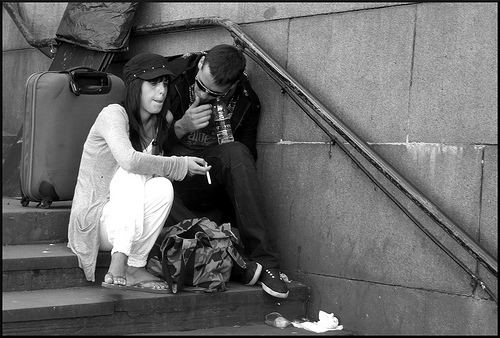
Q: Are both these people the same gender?
A: No, they are both male and female.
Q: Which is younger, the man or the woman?
A: The man is younger than the woman.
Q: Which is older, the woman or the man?
A: The woman is older than the man.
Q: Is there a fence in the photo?
A: No, there are no fences.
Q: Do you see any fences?
A: No, there are no fences.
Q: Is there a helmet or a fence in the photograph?
A: No, there are no fences or helmets.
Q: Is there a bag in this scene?
A: Yes, there is a bag.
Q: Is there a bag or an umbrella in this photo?
A: Yes, there is a bag.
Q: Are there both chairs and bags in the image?
A: No, there is a bag but no chairs.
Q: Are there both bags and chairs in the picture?
A: No, there is a bag but no chairs.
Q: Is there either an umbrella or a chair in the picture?
A: No, there are no chairs or umbrellas.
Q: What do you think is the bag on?
A: The bag is on the steps.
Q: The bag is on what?
A: The bag is on the steps.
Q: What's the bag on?
A: The bag is on the steps.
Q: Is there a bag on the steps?
A: Yes, there is a bag on the steps.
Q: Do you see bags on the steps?
A: Yes, there is a bag on the steps.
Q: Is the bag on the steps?
A: Yes, the bag is on the steps.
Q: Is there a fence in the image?
A: No, there are no fences.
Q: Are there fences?
A: No, there are no fences.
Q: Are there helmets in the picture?
A: No, there are no helmets.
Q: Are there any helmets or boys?
A: No, there are no helmets or boys.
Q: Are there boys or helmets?
A: No, there are no helmets or boys.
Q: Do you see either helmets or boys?
A: No, there are no helmets or boys.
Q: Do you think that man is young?
A: Yes, the man is young.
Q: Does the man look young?
A: Yes, the man is young.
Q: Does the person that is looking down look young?
A: Yes, the man is young.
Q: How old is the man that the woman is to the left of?
A: The man is young.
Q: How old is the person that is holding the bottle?
A: The man is young.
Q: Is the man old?
A: No, the man is young.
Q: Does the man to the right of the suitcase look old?
A: No, the man is young.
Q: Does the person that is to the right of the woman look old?
A: No, the man is young.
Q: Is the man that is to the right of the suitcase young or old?
A: The man is young.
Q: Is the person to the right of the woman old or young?
A: The man is young.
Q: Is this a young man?
A: Yes, this is a young man.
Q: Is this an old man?
A: No, this is a young man.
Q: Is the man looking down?
A: Yes, the man is looking down.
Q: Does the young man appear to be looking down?
A: Yes, the man is looking down.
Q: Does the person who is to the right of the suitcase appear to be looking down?
A: Yes, the man is looking down.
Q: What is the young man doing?
A: The man is looking down.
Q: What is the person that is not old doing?
A: The man is looking down.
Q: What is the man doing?
A: The man is looking down.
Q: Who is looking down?
A: The man is looking down.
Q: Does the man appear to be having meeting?
A: No, the man is looking down.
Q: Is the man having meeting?
A: No, the man is looking down.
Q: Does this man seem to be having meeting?
A: No, the man is looking down.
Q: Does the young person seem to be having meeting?
A: No, the man is looking down.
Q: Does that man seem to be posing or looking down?
A: The man is looking down.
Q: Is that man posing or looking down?
A: The man is looking down.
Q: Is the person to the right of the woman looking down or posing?
A: The man is looking down.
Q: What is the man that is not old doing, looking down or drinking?
A: The man is looking down.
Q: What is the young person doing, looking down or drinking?
A: The man is looking down.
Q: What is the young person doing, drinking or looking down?
A: The man is looking down.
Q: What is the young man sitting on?
A: The man is sitting on the steps.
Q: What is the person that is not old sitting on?
A: The man is sitting on the steps.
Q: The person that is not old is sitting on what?
A: The man is sitting on the steps.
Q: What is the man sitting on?
A: The man is sitting on the steps.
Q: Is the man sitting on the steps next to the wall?
A: Yes, the man is sitting on the steps.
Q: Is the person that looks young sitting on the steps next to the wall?
A: Yes, the man is sitting on the steps.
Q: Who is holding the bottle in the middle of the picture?
A: The man is holding the bottle.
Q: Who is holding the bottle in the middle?
A: The man is holding the bottle.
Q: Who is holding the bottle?
A: The man is holding the bottle.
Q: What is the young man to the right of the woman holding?
A: The man is holding the bottle.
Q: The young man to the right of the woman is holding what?
A: The man is holding the bottle.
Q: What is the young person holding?
A: The man is holding the bottle.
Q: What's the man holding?
A: The man is holding the bottle.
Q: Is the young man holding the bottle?
A: Yes, the man is holding the bottle.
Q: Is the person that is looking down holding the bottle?
A: Yes, the man is holding the bottle.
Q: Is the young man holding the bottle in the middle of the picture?
A: Yes, the man is holding the bottle.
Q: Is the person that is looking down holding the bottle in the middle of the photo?
A: Yes, the man is holding the bottle.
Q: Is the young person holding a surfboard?
A: No, the man is holding the bottle.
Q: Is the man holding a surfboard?
A: No, the man is holding the bottle.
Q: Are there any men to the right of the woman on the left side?
A: Yes, there is a man to the right of the woman.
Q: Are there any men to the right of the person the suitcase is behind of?
A: Yes, there is a man to the right of the woman.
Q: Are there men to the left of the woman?
A: No, the man is to the right of the woman.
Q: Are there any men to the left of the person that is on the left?
A: No, the man is to the right of the woman.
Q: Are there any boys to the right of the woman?
A: No, there is a man to the right of the woman.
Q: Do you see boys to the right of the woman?
A: No, there is a man to the right of the woman.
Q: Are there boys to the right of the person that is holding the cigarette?
A: No, there is a man to the right of the woman.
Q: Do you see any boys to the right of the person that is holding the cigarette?
A: No, there is a man to the right of the woman.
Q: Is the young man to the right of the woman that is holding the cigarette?
A: Yes, the man is to the right of the woman.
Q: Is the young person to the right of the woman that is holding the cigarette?
A: Yes, the man is to the right of the woman.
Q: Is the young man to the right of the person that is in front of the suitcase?
A: Yes, the man is to the right of the woman.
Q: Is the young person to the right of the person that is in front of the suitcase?
A: Yes, the man is to the right of the woman.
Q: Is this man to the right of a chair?
A: No, the man is to the right of the woman.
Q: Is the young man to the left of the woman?
A: No, the man is to the right of the woman.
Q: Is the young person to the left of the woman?
A: No, the man is to the right of the woman.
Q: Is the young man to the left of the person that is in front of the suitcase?
A: No, the man is to the right of the woman.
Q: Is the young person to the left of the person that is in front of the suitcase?
A: No, the man is to the right of the woman.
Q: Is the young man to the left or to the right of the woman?
A: The man is to the right of the woman.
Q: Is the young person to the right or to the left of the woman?
A: The man is to the right of the woman.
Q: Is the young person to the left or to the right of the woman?
A: The man is to the right of the woman.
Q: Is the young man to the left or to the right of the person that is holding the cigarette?
A: The man is to the right of the woman.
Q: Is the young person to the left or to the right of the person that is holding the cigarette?
A: The man is to the right of the woman.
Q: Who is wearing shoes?
A: The man is wearing shoes.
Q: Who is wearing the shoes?
A: The man is wearing shoes.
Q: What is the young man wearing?
A: The man is wearing shoes.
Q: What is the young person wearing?
A: The man is wearing shoes.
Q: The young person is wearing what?
A: The man is wearing shoes.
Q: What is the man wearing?
A: The man is wearing shoes.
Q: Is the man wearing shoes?
A: Yes, the man is wearing shoes.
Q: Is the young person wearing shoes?
A: Yes, the man is wearing shoes.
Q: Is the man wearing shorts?
A: No, the man is wearing shoes.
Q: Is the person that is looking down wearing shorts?
A: No, the man is wearing shoes.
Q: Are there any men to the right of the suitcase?
A: Yes, there is a man to the right of the suitcase.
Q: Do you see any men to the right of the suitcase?
A: Yes, there is a man to the right of the suitcase.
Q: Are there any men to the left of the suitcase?
A: No, the man is to the right of the suitcase.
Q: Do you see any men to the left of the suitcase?
A: No, the man is to the right of the suitcase.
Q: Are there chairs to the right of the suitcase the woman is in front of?
A: No, there is a man to the right of the suitcase.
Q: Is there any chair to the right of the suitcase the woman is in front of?
A: No, there is a man to the right of the suitcase.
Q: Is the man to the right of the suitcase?
A: Yes, the man is to the right of the suitcase.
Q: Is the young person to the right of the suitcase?
A: Yes, the man is to the right of the suitcase.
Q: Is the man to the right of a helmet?
A: No, the man is to the right of the suitcase.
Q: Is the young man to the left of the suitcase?
A: No, the man is to the right of the suitcase.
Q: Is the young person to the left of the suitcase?
A: No, the man is to the right of the suitcase.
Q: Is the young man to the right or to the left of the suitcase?
A: The man is to the right of the suitcase.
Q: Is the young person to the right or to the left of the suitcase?
A: The man is to the right of the suitcase.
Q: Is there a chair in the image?
A: No, there are no chairs.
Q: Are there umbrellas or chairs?
A: No, there are no chairs or umbrellas.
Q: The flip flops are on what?
A: The flip flops are on the steps.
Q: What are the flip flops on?
A: The flip flops are on the steps.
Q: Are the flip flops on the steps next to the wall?
A: Yes, the flip flops are on the steps.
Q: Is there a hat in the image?
A: Yes, there is a hat.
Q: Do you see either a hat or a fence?
A: Yes, there is a hat.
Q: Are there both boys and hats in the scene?
A: No, there is a hat but no boys.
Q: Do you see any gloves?
A: No, there are no gloves.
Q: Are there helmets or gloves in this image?
A: No, there are no gloves or helmets.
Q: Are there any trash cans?
A: No, there are no trash cans.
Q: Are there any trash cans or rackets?
A: No, there are no trash cans or rackets.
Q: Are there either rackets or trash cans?
A: No, there are no trash cans or rackets.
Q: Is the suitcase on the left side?
A: Yes, the suitcase is on the left of the image.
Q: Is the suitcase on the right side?
A: No, the suitcase is on the left of the image.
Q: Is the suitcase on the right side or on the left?
A: The suitcase is on the left of the image.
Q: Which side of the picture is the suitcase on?
A: The suitcase is on the left of the image.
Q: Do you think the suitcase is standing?
A: Yes, the suitcase is standing.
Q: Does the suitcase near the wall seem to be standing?
A: Yes, the suitcase is standing.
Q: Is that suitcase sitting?
A: No, the suitcase is standing.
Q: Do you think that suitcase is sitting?
A: No, the suitcase is standing.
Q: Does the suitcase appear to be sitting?
A: No, the suitcase is standing.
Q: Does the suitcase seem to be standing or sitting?
A: The suitcase is standing.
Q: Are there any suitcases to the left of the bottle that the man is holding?
A: Yes, there is a suitcase to the left of the bottle.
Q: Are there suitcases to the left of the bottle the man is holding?
A: Yes, there is a suitcase to the left of the bottle.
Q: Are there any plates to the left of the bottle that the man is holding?
A: No, there is a suitcase to the left of the bottle.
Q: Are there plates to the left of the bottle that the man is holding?
A: No, there is a suitcase to the left of the bottle.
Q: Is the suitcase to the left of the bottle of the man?
A: Yes, the suitcase is to the left of the bottle.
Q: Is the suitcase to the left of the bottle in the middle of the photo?
A: Yes, the suitcase is to the left of the bottle.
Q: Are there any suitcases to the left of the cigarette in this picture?
A: Yes, there is a suitcase to the left of the cigarette.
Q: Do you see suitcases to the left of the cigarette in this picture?
A: Yes, there is a suitcase to the left of the cigarette.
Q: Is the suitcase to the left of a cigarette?
A: Yes, the suitcase is to the left of a cigarette.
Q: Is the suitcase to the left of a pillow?
A: No, the suitcase is to the left of a cigarette.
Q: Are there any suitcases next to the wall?
A: Yes, there is a suitcase next to the wall.